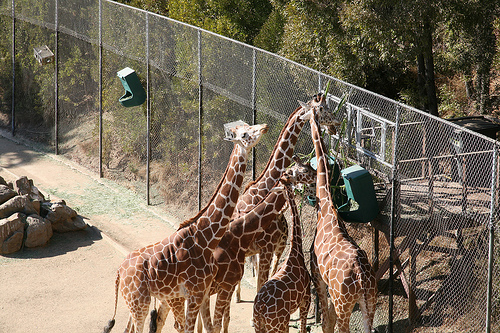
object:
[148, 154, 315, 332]
giraffe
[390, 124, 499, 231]
deck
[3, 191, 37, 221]
rock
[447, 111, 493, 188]
can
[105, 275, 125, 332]
tail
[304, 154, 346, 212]
feed box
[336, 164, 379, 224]
bins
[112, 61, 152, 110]
feeder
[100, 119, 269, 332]
giraffe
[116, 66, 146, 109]
bin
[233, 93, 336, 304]
giraffe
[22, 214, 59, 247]
rock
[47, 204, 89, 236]
rock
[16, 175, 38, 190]
rock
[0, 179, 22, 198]
rock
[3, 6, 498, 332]
enclosure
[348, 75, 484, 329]
platform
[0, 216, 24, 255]
rock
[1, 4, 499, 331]
fence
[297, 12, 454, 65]
trees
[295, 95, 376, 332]
giraffe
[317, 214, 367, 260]
back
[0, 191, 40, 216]
rock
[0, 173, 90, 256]
pile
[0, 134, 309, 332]
floor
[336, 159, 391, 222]
feeder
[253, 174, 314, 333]
giraffe